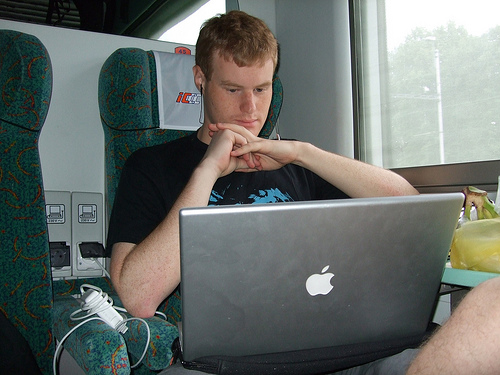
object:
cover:
[178, 191, 466, 362]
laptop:
[179, 191, 466, 362]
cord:
[50, 284, 167, 375]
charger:
[80, 289, 129, 335]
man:
[105, 10, 498, 375]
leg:
[406, 276, 500, 375]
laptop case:
[170, 320, 443, 375]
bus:
[0, 0, 500, 375]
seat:
[0, 28, 131, 375]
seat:
[93, 47, 283, 375]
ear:
[192, 64, 207, 94]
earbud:
[199, 76, 204, 124]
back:
[178, 192, 465, 362]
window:
[157, 0, 225, 40]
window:
[348, 0, 499, 169]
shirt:
[104, 126, 351, 258]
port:
[76, 240, 106, 271]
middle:
[37, 25, 107, 281]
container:
[449, 217, 500, 273]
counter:
[441, 267, 500, 288]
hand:
[193, 122, 313, 172]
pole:
[434, 49, 445, 164]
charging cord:
[51, 284, 167, 375]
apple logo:
[305, 265, 335, 297]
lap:
[170, 334, 430, 374]